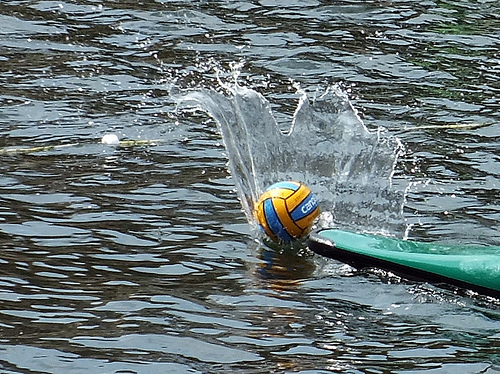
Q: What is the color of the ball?
A: Yellow and blue.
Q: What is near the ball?
A: A board.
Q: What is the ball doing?
A: Splashing.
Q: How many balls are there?
A: 1.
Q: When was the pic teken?
A: During the day.